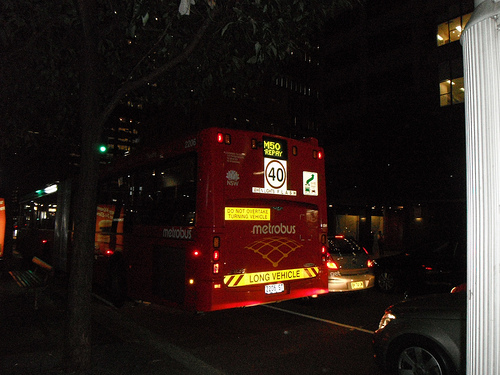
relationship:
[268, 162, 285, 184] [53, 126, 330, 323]
number on bus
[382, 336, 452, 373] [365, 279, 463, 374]
tire on car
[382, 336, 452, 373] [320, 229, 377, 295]
tire on car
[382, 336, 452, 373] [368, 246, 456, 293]
tire on car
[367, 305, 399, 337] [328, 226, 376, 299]
headlight on car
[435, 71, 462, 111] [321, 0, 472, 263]
window on building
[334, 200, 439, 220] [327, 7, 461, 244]
lights on building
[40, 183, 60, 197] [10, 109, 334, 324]
white light on bus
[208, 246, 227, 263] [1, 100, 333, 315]
light on bus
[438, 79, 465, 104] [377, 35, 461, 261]
light on building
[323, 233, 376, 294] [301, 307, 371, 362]
car on road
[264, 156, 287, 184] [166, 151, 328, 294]
forty on bus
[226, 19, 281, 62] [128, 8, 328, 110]
green leaves on tree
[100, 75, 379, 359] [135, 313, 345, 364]
bus on road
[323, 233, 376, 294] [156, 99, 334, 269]
car close to bus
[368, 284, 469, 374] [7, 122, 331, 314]
car behind bus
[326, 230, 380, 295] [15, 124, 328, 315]
car beside firetruck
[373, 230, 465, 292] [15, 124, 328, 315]
car beside firetruck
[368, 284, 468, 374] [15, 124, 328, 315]
car beside firetruck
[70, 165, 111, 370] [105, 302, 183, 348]
tree near street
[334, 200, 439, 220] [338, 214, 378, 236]
lights at entrance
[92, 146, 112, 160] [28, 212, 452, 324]
light on street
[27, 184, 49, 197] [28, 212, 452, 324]
light on street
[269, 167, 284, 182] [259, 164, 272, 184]
number has circle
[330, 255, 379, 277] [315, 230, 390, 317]
tail lights of a car